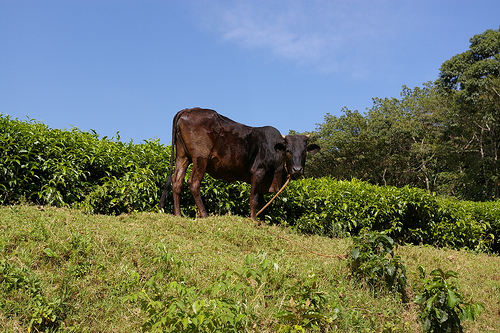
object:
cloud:
[0, 0, 499, 152]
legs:
[169, 153, 191, 217]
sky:
[0, 0, 499, 151]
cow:
[160, 107, 321, 225]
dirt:
[0, 203, 499, 333]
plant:
[412, 265, 486, 332]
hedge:
[0, 113, 499, 257]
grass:
[0, 205, 498, 332]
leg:
[186, 157, 212, 219]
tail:
[157, 109, 188, 210]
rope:
[243, 215, 348, 263]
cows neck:
[280, 137, 288, 178]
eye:
[283, 148, 292, 155]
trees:
[371, 79, 459, 192]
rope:
[254, 177, 295, 217]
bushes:
[431, 204, 499, 258]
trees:
[424, 27, 498, 161]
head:
[274, 133, 320, 182]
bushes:
[409, 265, 481, 332]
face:
[281, 134, 307, 176]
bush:
[345, 231, 407, 305]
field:
[0, 202, 498, 333]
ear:
[305, 143, 322, 156]